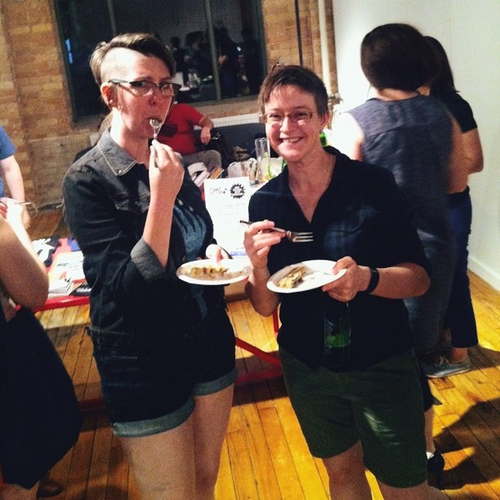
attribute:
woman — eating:
[125, 83, 152, 142]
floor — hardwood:
[246, 341, 286, 450]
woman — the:
[63, 33, 236, 499]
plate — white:
[178, 256, 253, 284]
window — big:
[42, 1, 267, 132]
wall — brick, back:
[0, 2, 339, 206]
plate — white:
[262, 257, 350, 292]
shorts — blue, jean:
[87, 323, 239, 439]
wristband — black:
[358, 257, 386, 298]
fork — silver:
[236, 218, 313, 242]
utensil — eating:
[148, 109, 166, 149]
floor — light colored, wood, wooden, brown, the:
[28, 265, 494, 498]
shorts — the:
[98, 324, 243, 446]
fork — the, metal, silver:
[231, 219, 311, 251]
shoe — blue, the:
[427, 354, 477, 380]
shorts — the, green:
[272, 345, 437, 497]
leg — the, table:
[224, 323, 286, 369]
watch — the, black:
[364, 265, 384, 293]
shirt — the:
[62, 127, 246, 367]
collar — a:
[94, 126, 135, 178]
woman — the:
[232, 64, 435, 497]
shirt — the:
[337, 95, 459, 216]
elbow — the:
[3, 217, 63, 315]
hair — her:
[355, 22, 452, 108]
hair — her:
[357, 18, 431, 96]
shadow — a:
[431, 382, 499, 487]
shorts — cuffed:
[82, 318, 247, 442]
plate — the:
[262, 252, 351, 290]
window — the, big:
[39, 1, 281, 123]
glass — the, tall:
[249, 136, 269, 178]